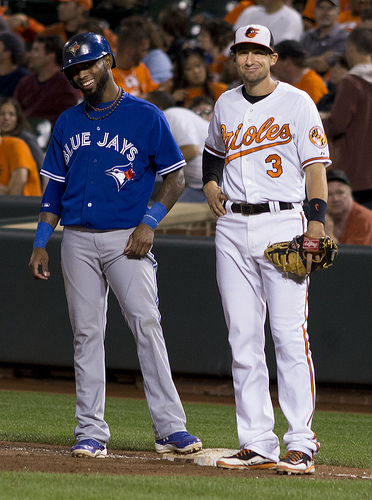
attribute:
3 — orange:
[267, 154, 286, 181]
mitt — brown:
[272, 244, 303, 278]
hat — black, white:
[329, 167, 349, 186]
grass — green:
[2, 395, 47, 441]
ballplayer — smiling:
[30, 38, 207, 458]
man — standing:
[332, 27, 371, 175]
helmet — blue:
[60, 32, 112, 73]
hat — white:
[230, 24, 273, 49]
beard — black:
[82, 76, 107, 101]